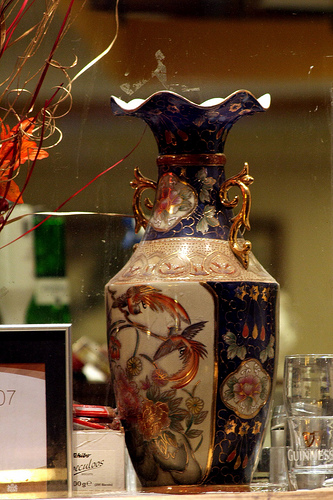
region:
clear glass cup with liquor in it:
[282, 353, 330, 484]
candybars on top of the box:
[67, 401, 122, 430]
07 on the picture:
[0, 381, 18, 415]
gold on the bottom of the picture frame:
[3, 469, 63, 480]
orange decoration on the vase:
[120, 287, 191, 323]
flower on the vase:
[219, 364, 270, 414]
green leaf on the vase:
[222, 325, 246, 362]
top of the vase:
[111, 88, 277, 120]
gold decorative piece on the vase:
[215, 159, 256, 271]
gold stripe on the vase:
[206, 368, 221, 438]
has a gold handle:
[214, 159, 264, 271]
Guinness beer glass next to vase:
[285, 406, 332, 486]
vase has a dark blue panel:
[197, 279, 283, 490]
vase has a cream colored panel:
[112, 281, 206, 498]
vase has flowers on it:
[107, 283, 277, 480]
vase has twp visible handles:
[119, 156, 288, 271]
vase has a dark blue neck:
[107, 81, 277, 247]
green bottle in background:
[20, 211, 78, 332]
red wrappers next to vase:
[73, 390, 111, 439]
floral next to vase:
[0, 2, 131, 260]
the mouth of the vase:
[104, 85, 275, 121]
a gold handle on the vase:
[218, 161, 259, 270]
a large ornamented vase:
[95, 78, 291, 490]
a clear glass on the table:
[279, 350, 331, 492]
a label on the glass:
[284, 431, 331, 464]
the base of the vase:
[138, 477, 254, 498]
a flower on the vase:
[183, 392, 207, 416]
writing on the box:
[72, 449, 117, 492]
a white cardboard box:
[71, 428, 142, 490]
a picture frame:
[0, 315, 81, 499]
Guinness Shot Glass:
[281, 411, 331, 486]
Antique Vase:
[104, 91, 268, 497]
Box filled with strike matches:
[69, 400, 128, 498]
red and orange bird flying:
[152, 326, 214, 394]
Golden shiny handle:
[216, 165, 262, 271]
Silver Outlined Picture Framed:
[1, 318, 78, 497]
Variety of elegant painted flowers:
[111, 366, 182, 462]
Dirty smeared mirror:
[286, 58, 330, 161]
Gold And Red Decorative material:
[7, 72, 77, 160]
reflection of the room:
[35, 213, 109, 334]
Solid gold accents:
[219, 162, 262, 270]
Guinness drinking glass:
[281, 351, 331, 484]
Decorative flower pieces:
[0, 0, 104, 175]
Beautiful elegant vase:
[108, 88, 283, 492]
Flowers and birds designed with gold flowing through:
[104, 282, 216, 474]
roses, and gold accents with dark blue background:
[107, 82, 279, 288]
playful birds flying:
[111, 278, 213, 382]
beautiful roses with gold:
[111, 368, 205, 471]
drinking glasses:
[280, 351, 331, 494]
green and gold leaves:
[193, 203, 221, 237]